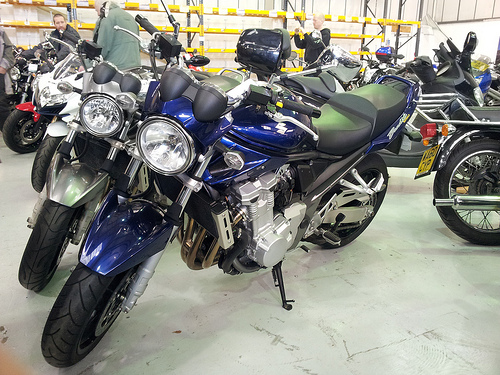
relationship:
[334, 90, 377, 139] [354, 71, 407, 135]
divider between seating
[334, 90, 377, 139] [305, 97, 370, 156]
divider between seating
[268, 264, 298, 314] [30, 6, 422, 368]
kickstand on motorcycle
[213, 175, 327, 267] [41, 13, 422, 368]
engine on bike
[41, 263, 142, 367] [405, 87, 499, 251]
wheel on motorcycle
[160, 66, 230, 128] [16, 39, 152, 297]
black lights by motorcycle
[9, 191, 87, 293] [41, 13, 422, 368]
tire on bike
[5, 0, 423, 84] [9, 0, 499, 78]
railing by wall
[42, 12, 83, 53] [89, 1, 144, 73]
man talking to man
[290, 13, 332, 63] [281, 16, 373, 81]
man wears black shirt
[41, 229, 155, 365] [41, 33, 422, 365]
wheel on bike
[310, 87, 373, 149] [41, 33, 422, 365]
seat on bike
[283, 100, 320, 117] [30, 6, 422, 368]
handle on motorcycle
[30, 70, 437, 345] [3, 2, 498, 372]
mototrcycle sitting in warehouse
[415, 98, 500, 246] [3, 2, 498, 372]
mototrcycle sitting in warehouse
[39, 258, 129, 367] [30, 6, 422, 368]
tire on motorcycle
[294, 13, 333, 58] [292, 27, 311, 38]
man looking at something in h hands